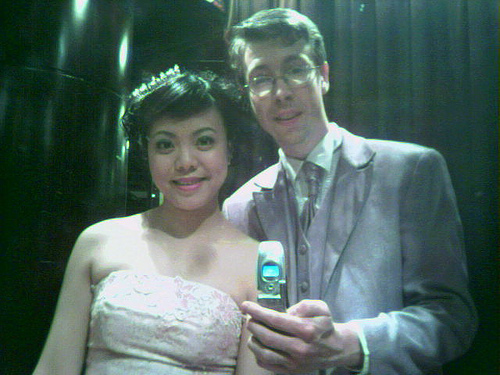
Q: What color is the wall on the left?
A: Black.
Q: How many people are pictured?
A: Two.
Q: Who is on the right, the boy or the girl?
A: The boy.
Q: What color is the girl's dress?
A: White.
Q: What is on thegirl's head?
A: Tiara.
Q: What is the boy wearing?
A: A tuxedo.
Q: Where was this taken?
A: At prom.